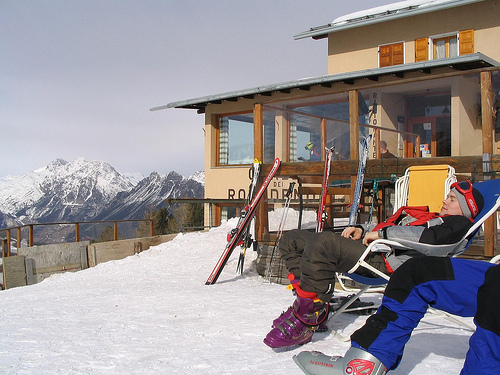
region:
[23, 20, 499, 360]
A picture of a ski resort.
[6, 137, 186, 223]
Snow covered mountains in distance.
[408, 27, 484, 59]
Shutters on a window.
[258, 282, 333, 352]
A pair of purple ski boots.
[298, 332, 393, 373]
A silver ski boot with red design.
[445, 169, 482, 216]
A pair of red ski goggles.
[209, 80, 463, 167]
Large square windows in a building.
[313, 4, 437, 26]
Snow on the roof.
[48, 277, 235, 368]
Snow on the ground.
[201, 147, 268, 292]
Skis leaned against a frame.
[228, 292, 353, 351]
purple ski boots attached to skier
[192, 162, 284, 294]
skis lean on a mountain chalet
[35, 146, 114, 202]
snow covered mountain tops in distance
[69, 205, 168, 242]
wooden fence erected for safety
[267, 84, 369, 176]
people indoors at mountain chalet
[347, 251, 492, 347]
black and blue ski pants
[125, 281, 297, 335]
packed snow around mountain chalet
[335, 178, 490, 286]
resting outdoors in ski outfit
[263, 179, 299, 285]
ski poles rest on ledge out of doors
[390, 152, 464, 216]
stacked bright yellow chairs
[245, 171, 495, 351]
man reclining outdoors in chair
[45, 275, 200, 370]
white snow on the ground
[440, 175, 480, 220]
man wearing ski goggles on his head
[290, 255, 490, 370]
person wearing blue and black ski pants is partially visible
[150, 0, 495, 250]
multistory building near reclining man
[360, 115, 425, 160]
person inside building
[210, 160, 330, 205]
dark words printed on building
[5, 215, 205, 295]
wood and glass wall near snow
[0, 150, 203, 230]
snow on mountains in the distance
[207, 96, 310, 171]
striped curtains of windows in building pulled back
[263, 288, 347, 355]
purple skates worn by a man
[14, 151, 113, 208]
snow capped mountains next to a house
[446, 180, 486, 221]
red snow goggles rest on man's head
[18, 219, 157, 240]
a wooden fence on the side of a house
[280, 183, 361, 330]
black pants covering the legs of a man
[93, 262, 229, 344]
white snow on the ground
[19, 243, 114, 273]
a stone base supporting a fence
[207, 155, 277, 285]
red skis leaning against a porch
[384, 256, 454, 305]
a black patch on blue pants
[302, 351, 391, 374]
gray snow shoes on a foot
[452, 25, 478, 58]
brown shutter on a window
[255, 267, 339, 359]
purple ski boots on feet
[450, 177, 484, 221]
ski goggles on a persons head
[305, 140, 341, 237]
skis against a fence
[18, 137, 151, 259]
mountains in the background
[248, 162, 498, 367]
person in a chair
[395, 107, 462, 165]
doorway of a building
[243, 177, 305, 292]
ski poles near skis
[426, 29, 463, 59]
windows on a building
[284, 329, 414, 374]
silver and red ski boot on a person